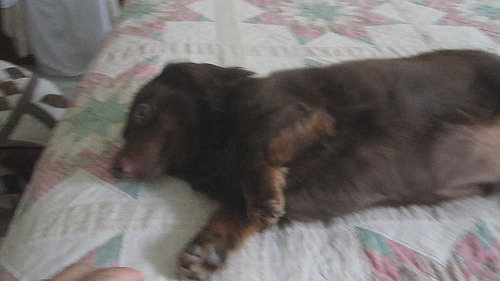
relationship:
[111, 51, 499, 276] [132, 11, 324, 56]
dog laying on quilt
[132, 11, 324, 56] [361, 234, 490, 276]
quilt mutli colored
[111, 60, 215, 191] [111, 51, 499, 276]
head of dog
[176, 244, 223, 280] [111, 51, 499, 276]
paw of dog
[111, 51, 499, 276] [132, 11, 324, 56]
dog on quilt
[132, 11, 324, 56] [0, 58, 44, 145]
quilt on floor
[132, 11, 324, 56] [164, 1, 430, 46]
quilt on bed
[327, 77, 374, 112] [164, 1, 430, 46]
brown dog on bed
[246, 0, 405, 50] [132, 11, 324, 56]
star shaped pattern on quilt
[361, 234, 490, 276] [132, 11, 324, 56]
pattern on quilt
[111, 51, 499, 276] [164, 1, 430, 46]
dog on bed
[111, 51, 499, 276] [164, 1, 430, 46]
dog lying on bed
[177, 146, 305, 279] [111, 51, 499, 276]
legs of dog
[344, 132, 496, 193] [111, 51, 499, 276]
belly of dog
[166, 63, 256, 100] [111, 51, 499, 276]
ear of dog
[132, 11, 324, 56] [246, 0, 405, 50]
quilt has pattern of star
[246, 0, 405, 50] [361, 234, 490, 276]
star has multi colored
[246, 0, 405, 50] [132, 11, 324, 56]
star on a quilt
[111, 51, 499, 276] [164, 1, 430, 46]
dog laying on bed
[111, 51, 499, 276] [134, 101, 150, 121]
dog has an eye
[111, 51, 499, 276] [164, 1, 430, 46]
dog relaxing on bed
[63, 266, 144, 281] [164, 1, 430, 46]
hand on bed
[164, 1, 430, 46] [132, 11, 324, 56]
bed with quilt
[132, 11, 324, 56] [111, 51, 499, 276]
quilt under dog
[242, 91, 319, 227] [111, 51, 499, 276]
leg on dog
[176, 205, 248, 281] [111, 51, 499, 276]
right leg of dog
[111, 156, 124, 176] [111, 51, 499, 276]
nose of a dog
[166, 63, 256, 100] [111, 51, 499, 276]
ear of a dog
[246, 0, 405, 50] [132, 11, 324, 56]
star pattern on quilt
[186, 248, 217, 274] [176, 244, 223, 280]
bottom of paw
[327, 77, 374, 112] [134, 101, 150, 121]
brown dog eye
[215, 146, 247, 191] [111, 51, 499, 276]
chest of dog